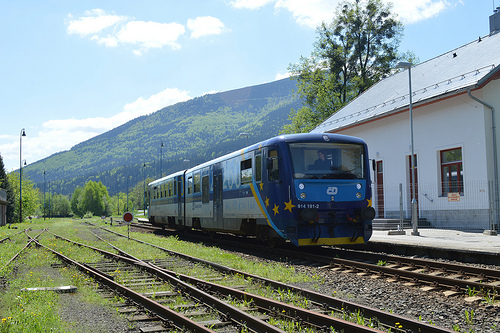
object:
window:
[286, 143, 365, 180]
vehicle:
[145, 132, 377, 248]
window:
[200, 173, 212, 203]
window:
[440, 148, 464, 163]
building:
[303, 7, 500, 238]